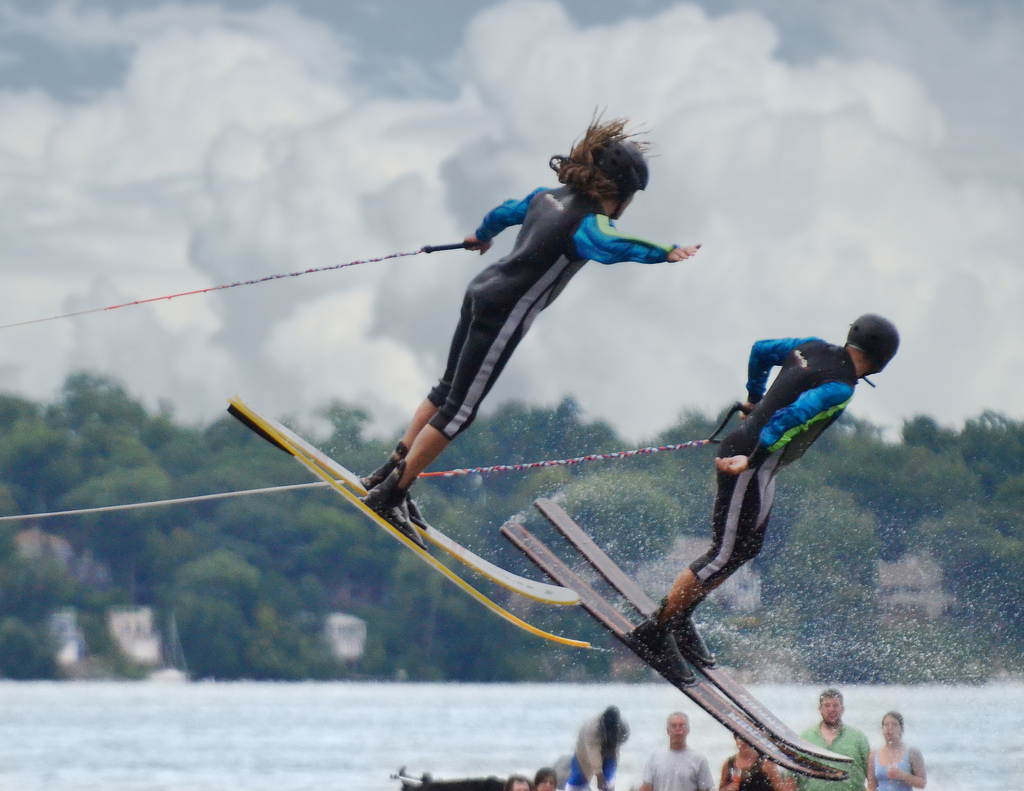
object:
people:
[361, 108, 701, 551]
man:
[781, 689, 879, 790]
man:
[627, 313, 902, 687]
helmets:
[846, 313, 901, 371]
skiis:
[495, 497, 856, 783]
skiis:
[222, 398, 591, 646]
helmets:
[548, 140, 647, 215]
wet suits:
[688, 337, 855, 589]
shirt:
[792, 727, 869, 791]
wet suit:
[429, 186, 675, 438]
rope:
[0, 402, 744, 521]